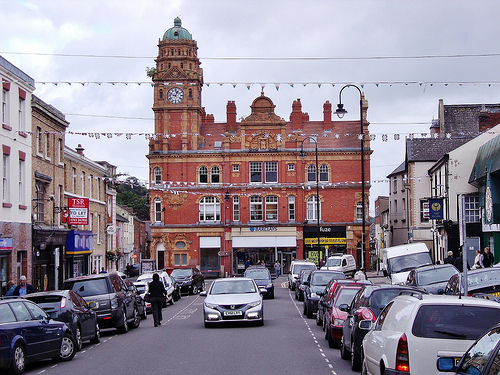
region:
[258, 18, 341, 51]
clouds above the building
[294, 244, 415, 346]
cars on the ground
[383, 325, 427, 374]
light on back of car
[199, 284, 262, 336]
front of the car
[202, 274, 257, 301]
window on the car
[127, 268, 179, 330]
person walking down street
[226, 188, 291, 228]
windows on the building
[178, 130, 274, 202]
red building in distance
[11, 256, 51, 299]
people walking down the street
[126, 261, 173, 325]
lady wearing dark colors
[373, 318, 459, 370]
White car on side of road.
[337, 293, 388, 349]
Black car on side of road.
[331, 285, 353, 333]
Red car on side of road.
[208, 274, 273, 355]
Silver car driving on road.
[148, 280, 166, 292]
Person wearing black shirt.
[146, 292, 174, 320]
Person wearing dark pants.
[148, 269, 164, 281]
Person has dark hair.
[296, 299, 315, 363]
White lines marking road.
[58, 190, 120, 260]
Red and white sign attached to building.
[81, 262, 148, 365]
Silver car on side of road.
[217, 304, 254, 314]
part of a plate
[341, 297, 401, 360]
side of a car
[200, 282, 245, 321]
front of a car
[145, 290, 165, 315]
part of a trouser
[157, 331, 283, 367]
the road is black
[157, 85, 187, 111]
the clokc is on the wall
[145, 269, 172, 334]
the woman is walking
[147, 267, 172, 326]
the woman is wearing black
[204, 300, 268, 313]
the cr has headlights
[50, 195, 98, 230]
the banner is red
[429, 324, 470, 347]
the wiper is on the backwindow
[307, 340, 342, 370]
the lines are white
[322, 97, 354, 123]
the lamp is off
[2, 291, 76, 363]
the car is blue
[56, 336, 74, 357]
the tire of a car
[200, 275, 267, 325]
a small gray car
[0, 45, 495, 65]
a long electrical power line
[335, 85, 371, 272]
a tall black lamp pole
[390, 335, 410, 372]
a red taillight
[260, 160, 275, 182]
a window of a building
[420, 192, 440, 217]
a blue and yellow sign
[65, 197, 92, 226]
a red and white sign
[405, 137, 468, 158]
part of a rooftop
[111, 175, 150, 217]
part of a large green tree